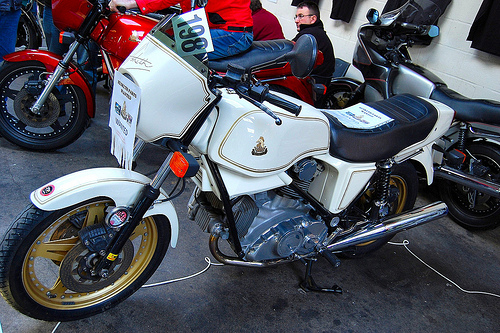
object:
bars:
[195, 94, 333, 180]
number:
[177, 12, 214, 54]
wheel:
[0, 47, 94, 153]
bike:
[3, 7, 455, 323]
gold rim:
[23, 199, 160, 311]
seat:
[317, 93, 437, 165]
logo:
[247, 137, 273, 160]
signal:
[166, 149, 201, 181]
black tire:
[0, 196, 173, 322]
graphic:
[112, 101, 134, 126]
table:
[0, 0, 500, 333]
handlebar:
[223, 71, 306, 126]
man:
[288, 0, 336, 82]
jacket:
[291, 20, 338, 90]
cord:
[138, 252, 225, 292]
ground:
[0, 89, 498, 331]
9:
[176, 26, 210, 38]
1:
[173, 12, 200, 25]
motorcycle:
[2, 1, 322, 155]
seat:
[429, 84, 499, 126]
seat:
[208, 38, 293, 73]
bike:
[326, 0, 500, 232]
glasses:
[284, 2, 335, 94]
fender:
[25, 37, 90, 126]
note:
[317, 102, 393, 131]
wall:
[260, 0, 499, 101]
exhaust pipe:
[208, 199, 448, 268]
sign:
[106, 69, 142, 170]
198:
[175, 15, 207, 52]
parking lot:
[0, 0, 500, 333]